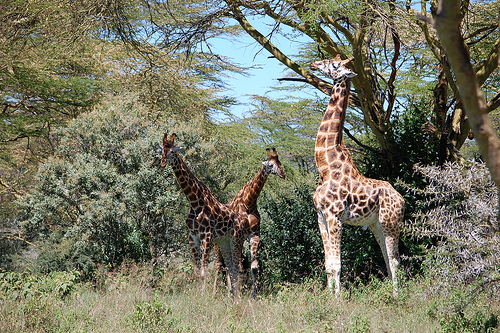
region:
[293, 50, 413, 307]
The giraffe is tall.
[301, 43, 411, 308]
The giraffe is statuesque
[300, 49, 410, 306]
The giraffe is brown and white.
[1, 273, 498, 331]
The vegetation is overgrown.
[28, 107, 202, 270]
The tree is green.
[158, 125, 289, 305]
Two giraffes standing together.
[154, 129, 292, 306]
One giraffe in front of the other.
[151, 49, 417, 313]
Three giraffes in the wild.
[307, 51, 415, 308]
The giraffe looks very proper.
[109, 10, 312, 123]
The sky is blue and clear.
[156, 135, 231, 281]
Giraffe in the photo.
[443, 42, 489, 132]
Tree trunk in the picture.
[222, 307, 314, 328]
Dry vegetation in the picture.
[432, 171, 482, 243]
Thorny shrubs in the picture.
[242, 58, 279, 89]
Clear skies in the picture.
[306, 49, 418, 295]
A giraffe feeding on leaves.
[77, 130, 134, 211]
gray leaves in the picture.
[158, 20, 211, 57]
Dry twigs in the picture.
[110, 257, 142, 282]
Red flowers in the photo.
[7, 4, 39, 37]
A nest on the tree.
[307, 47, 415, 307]
this is a giraffe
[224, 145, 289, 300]
this is a giraffe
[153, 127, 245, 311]
this is a giraffe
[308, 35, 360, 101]
the head of a giraffe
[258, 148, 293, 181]
the head of a giraffe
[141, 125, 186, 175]
the head of a giraffe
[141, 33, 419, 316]
three giraffes in the forest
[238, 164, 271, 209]
the neck of a giraffe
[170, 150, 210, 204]
the neck of a giraffe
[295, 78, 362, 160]
the neck of a giraffe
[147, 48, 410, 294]
three giraffe are outside.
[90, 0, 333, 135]
the sky is blue.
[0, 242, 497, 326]
The grass is long.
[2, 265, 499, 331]
the grass is green and brown.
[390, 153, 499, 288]
the bush is purple.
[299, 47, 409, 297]
Giraffe is brown and white.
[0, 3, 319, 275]
Trees in the distance.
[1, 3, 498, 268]
The leaves are green.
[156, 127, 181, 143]
The giraffe has two horns.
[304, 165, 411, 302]
The giraffe has four legs.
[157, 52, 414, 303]
Three giraffes standing together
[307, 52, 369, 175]
A giraffe stretching his neck to the sky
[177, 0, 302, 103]
A clear blue sky behind the trees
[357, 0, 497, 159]
The branches of trees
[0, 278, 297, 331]
Tall grass and plants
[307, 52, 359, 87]
The head of a giraffe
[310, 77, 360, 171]
A giraffe's long spotted neck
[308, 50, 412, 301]
A giraffe standing still and tall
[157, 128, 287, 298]
Two giraffes walking near each other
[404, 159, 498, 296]
A spiny purple plant